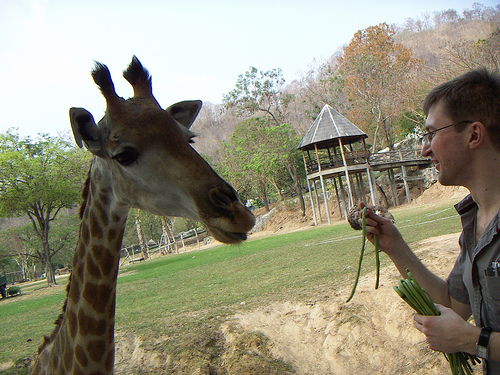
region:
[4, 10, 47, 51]
white clouds in blue sky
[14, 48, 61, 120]
white clouds in blue sky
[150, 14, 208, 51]
white clouds in blue sky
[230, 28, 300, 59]
white clouds in blue sky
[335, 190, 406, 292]
green celery held by man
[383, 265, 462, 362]
green celery held by man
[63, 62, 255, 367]
brown spotted giraffe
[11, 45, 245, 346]
tan and brown spotted giraffe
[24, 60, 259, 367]
spotted giraffe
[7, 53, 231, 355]
giraffe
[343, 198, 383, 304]
green plants in a man's right hand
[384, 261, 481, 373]
bunch of plants in a man's left hand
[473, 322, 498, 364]
watch on man's left hand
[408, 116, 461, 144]
glasses on a man's face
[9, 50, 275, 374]
giraffe next to a man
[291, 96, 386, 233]
covered observation area near a giraffes habitat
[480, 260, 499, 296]
pocket on man's work shirt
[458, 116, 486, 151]
man's left ear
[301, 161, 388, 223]
stilts on a wooden platform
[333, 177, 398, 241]
bird behind man's hand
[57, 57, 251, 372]
head and neck of a giraffe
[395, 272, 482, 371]
food to feed the giraffe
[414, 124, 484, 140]
eye glasses on man's face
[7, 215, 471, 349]
green grass on the ground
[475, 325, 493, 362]
wrist watch on the man's hand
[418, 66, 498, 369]
man feeding a giraffe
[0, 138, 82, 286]
mature tall tree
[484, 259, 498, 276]
pens in the shirt pocket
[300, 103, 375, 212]
wooden viewing platform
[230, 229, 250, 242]
giraffe's tongue sticking out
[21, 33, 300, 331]
giraffe at the zoo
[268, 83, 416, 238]
gazebo at the zoo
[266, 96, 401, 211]
walkway out into the zoo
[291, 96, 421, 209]
walk way out into the giraffe exhibit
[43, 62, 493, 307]
man feeding the giraffe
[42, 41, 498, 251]
giraffe staring at man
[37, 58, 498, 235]
man staring at giraffe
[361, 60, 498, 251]
man wearing black framed glasses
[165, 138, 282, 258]
giraffe has a beard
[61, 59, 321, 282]
giraffe sticking his tongue out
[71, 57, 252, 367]
giraffe is in photo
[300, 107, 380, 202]
wooden gazebo in background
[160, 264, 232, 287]
green grass in the background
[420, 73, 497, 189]
man is smiling in photo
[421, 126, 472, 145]
man is wearing glasses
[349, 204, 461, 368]
man is holding green vegetation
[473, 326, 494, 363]
man has a watch on arm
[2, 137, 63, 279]
tall tree in the background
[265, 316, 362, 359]
the sand is tan in color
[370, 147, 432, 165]
the walkway is wooden